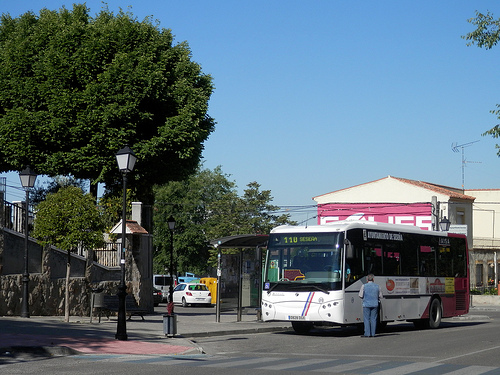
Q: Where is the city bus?
A: On a paved road.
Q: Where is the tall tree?
A: On the left.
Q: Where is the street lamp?
A: Over the street.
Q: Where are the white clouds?
A: In the sky.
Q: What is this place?
A: A bus stop.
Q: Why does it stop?
A: To load and unload passengers.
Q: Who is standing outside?
A: The driver.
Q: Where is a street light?
A: In front of the bus.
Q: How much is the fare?
A: Depends on the city.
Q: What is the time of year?
A: Summer.